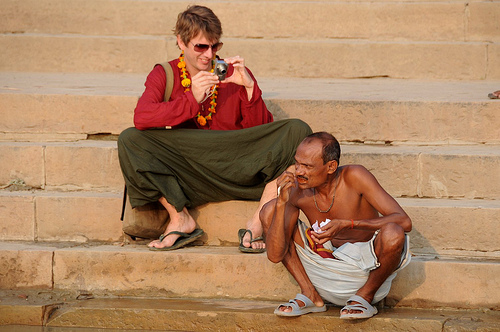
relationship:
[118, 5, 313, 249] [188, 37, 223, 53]
man with sunglasses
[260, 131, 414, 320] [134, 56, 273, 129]
man with no shirt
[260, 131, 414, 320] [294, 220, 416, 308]
man wearing shorts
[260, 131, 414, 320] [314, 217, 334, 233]
man has white object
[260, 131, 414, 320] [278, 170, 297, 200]
man has hand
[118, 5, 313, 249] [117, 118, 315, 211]
man wearing pants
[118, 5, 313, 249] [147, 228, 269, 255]
man wearing sandals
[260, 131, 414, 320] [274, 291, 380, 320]
man wearing sandals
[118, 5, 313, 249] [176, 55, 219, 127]
man wearing necklace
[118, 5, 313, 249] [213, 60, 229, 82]
man using camera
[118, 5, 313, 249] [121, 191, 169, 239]
man has bag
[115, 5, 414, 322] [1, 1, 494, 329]
men on steps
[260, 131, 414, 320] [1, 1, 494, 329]
man on steps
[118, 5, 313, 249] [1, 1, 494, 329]
man sitting on steps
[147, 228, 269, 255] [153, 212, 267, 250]
sandals on feet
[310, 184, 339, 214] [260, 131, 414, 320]
necklace on man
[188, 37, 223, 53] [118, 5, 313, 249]
sunglasses on man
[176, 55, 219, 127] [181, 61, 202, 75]
necklace on neck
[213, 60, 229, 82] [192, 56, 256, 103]
camera in hands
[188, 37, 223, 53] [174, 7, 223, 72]
sunglasses on head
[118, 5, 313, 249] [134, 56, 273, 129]
man wearing shirt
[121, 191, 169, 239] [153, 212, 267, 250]
bag behind feet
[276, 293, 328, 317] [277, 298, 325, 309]
sandal on foot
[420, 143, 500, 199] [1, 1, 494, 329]
bricks on steps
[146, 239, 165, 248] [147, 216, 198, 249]
toes on a foot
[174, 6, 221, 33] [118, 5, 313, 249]
hair on man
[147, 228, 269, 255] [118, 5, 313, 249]
sandals on man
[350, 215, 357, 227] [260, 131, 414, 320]
bracelet on man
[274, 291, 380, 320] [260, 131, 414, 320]
sandals on man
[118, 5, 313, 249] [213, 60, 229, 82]
man has camera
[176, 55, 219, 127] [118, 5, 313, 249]
necklace on man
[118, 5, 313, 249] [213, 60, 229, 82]
man taking picture with camera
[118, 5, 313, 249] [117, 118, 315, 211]
man in pants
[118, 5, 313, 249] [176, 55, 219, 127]
man has necklace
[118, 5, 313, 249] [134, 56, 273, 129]
man has red shirt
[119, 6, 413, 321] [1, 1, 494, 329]
men on steps